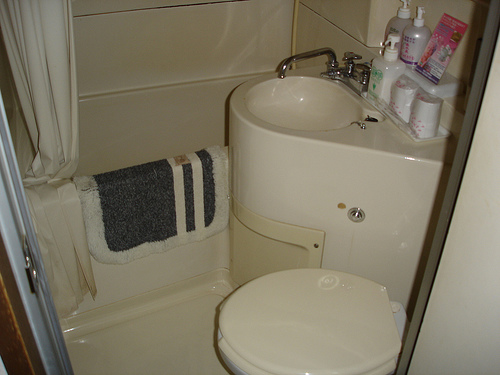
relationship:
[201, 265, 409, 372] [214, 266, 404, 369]
toilet has lid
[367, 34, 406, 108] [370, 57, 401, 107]
dispenser has soap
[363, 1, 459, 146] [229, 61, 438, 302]
supplies on a sink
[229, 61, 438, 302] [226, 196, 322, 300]
sink has storage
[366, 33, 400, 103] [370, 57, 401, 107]
bottle has soap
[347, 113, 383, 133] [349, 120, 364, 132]
stopper has chain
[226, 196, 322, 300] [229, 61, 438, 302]
storage in sink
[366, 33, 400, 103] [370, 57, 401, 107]
bottle of soap